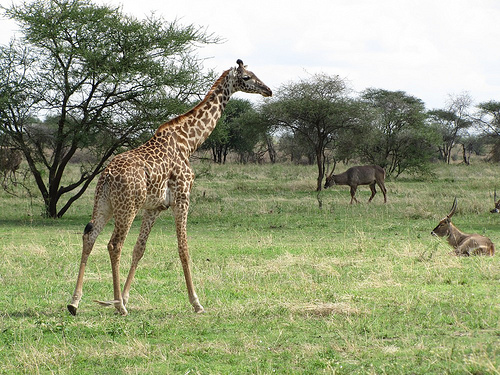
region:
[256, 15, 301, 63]
white clouds in blue sky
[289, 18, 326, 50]
white clouds in blue sky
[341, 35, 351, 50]
white clouds in blue sky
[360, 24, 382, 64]
white clouds in blue sky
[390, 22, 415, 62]
white clouds in blue sky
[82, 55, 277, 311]
brown spotted giraffe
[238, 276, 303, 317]
short yellolw and green grass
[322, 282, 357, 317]
short yellolw and green grass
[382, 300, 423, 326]
short yellolw and green grass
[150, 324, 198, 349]
short yellolw and green grass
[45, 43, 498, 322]
several animals on grassy plain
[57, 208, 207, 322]
four brown and white giraffe legs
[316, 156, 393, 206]
one brown wild animal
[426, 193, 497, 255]
one light colored sitting gazelle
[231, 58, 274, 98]
one brown and white giraffe head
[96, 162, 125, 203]
one brown and white giraffe behind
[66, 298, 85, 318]
one back giraffe hoof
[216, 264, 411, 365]
brown and green grassy field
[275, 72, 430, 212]
brown animal in front of trees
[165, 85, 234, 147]
one brown and white giraffe neck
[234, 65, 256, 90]
Giraffe has dark eye.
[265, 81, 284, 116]
Giraffe has black nose.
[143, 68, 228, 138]
Brown hair on giraffe's neck.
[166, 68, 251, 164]
Giraffe has long neck.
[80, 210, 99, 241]
Black hair on tip of giraffe's tail.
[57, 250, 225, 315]
Bottom of giraffe's legs are white.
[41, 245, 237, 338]
Giraffe standing in grassy area.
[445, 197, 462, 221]
Animal has large horns.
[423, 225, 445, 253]
Animal has black nose.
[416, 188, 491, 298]
Animal is sitting in grass.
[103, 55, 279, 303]
brown giraffe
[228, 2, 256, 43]
white clouds in blue sky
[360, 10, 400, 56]
white clouds in blue sky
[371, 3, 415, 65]
white clouds in blue sky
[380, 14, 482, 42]
white clouds in blue sky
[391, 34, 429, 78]
white clouds in blue sky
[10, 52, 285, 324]
the giraffe is walking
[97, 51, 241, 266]
the giraffe is tan and brown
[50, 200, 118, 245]
the tip of the tail is black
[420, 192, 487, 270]
animal is resting on the grass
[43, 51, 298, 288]
the giraffe is tall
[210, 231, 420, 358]
the grass is high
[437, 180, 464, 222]
the animal has horns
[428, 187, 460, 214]
the horns are pointy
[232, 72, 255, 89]
the eye is black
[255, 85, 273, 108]
the mouth is closed